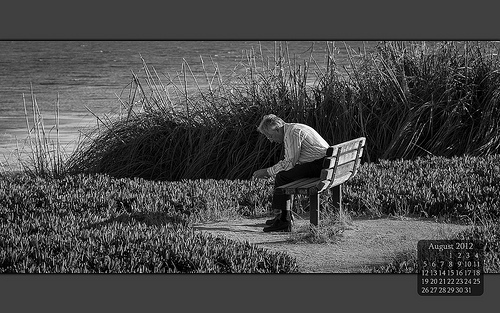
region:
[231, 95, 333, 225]
Elderly man on park bench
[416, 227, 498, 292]
August 2012 calender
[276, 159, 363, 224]
Wooden bench on square platform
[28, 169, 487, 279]
Medium length cut grass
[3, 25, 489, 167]
Calm waters in background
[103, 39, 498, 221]
Tall green grass to the right of man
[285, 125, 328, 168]
Striped button down shirt on man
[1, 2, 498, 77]
Borders on the picture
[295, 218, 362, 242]
Overgrown grass under bench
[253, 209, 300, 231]
Dark shoes on sitting man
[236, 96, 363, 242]
older man sitting down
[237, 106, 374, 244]
older man sitting on a bench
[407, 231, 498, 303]
August 2012 calendar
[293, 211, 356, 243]
weeds growing around the bench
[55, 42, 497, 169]
patch of long grass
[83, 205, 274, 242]
man's shadow on the ground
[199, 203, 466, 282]
small slab of concrete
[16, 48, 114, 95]
small ripples in the water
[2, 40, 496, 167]
body of water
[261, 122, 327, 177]
striped long sleeved shirt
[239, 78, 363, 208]
man on the bench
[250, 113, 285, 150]
head of the man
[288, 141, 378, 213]
bench below the man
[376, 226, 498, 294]
calender in the bottom right corner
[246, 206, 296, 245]
shoes on the man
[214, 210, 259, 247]
ground below the man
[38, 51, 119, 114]
water next to the man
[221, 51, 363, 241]
man looking down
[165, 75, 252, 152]
tall grass next to man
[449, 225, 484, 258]
the year 2012 in bottom right corner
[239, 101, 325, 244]
man leaning on his knees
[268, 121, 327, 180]
long sleeved striped shirt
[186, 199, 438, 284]
small slab of concrete surrounded by grass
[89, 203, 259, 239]
shadow from the man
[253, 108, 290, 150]
head angled down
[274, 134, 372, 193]
the bench is wood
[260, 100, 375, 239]
the man is sitting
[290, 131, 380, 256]
the bench on pavement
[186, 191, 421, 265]
pavement in the grass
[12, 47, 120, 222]
grass is beside water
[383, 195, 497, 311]
calendar in the corner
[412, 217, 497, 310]
the calendar says August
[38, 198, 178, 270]
the grass is cut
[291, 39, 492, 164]
the grasses are tall